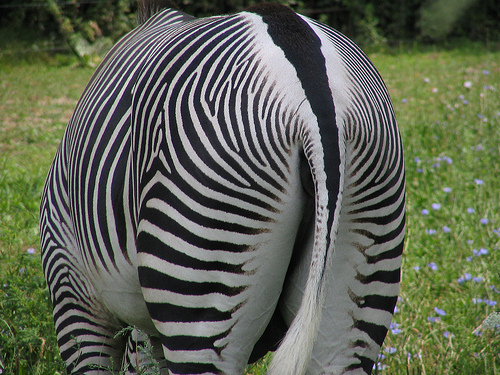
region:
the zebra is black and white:
[40, 9, 402, 371]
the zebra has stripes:
[39, 10, 406, 371]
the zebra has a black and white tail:
[264, 90, 346, 372]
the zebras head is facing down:
[41, 5, 406, 370]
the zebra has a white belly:
[94, 280, 151, 337]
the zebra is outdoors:
[43, 10, 405, 371]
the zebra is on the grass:
[41, 6, 407, 369]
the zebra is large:
[43, 5, 407, 369]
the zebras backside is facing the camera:
[39, 7, 404, 372]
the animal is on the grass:
[34, 10, 404, 368]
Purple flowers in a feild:
[458, 269, 490, 291]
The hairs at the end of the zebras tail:
[273, 289, 324, 374]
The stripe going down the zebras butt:
[264, 3, 341, 310]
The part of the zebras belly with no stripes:
[106, 278, 170, 338]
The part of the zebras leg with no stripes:
[228, 212, 283, 362]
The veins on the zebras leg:
[252, 299, 273, 320]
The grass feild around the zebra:
[7, 116, 34, 356]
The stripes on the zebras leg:
[135, 125, 288, 371]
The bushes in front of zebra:
[357, 5, 488, 51]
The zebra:
[39, 5, 409, 373]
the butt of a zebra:
[149, 70, 446, 350]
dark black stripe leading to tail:
[250, 4, 360, 203]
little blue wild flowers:
[400, 133, 497, 278]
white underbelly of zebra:
[79, 259, 188, 341]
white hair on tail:
[274, 285, 331, 373]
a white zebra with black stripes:
[45, 46, 447, 373]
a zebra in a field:
[25, 25, 498, 358]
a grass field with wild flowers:
[12, 42, 497, 372]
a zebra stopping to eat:
[37, 14, 485, 374]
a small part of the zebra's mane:
[129, 2, 176, 27]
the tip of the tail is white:
[259, 285, 339, 362]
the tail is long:
[242, 112, 357, 362]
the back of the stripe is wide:
[260, 2, 355, 232]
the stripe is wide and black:
[251, 1, 356, 231]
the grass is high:
[377, 42, 479, 341]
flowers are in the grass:
[410, 95, 484, 327]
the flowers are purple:
[424, 145, 499, 346]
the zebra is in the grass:
[35, 2, 429, 349]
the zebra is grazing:
[2, 0, 423, 350]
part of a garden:
[458, 205, 471, 217]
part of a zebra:
[347, 310, 349, 313]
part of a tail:
[302, 328, 317, 354]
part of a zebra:
[215, 268, 228, 284]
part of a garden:
[421, 172, 438, 199]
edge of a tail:
[318, 246, 321, 258]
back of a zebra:
[218, 202, 234, 225]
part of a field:
[421, 183, 436, 223]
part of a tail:
[308, 305, 328, 328]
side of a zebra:
[366, 258, 380, 275]